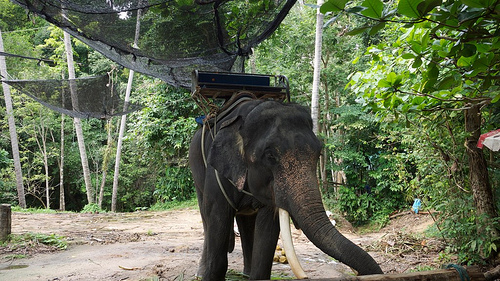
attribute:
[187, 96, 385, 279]
elephant — grey, forward, gray, large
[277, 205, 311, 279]
tusk — white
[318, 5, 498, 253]
tree — green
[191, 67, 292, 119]
seat — blue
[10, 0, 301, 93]
net — black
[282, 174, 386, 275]
trunk — long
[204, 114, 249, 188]
ear — large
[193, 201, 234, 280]
leg — cylindrical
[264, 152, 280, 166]
eye — small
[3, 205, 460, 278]
ground — brown, tan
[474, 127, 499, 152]
cloth — red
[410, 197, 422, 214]
ribbon — blue